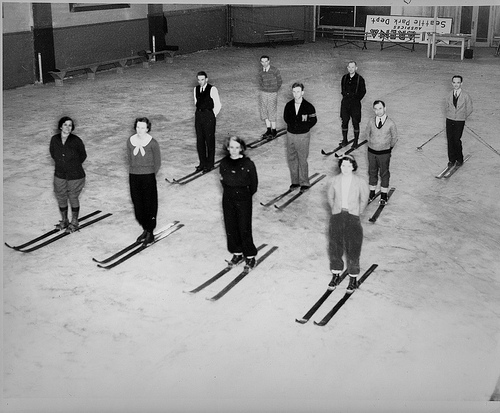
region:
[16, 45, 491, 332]
this group has been sentenced to ski lessons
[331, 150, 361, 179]
this young lady has a hair band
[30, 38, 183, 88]
a bench to one side of the rink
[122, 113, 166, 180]
this young lady's blouse has a bow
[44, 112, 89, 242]
this young lady is wearing jodhpurs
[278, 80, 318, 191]
this young man is wearing a varsity sweater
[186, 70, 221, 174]
this young man is nattily dressed in a vest and tie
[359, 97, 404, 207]
this young man is wearing a vest and tie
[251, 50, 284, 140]
this young man is wearing short pants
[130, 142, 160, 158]
part of a scarf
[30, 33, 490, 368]
The people are taking a ski class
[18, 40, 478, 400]
The people are all lined up together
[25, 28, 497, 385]
The people are all wearing ski boots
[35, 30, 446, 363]
The people are all using snow skis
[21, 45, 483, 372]
The people are planning to snow ski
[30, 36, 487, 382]
The people are male and female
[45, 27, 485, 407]
The people are standing in the snow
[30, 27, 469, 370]
The people are enjoying the day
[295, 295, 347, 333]
black skis on the ground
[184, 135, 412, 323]
two women on skis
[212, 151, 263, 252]
black suit on woman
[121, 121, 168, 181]
grey and white top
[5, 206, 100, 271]
black skis on the ground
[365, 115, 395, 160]
black tie under vest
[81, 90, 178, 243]
A person on a skate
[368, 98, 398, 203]
A person on a skate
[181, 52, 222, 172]
A person on a skate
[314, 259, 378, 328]
black ski on snow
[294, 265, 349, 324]
black ski on snow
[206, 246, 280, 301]
black ski on snow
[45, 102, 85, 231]
a person is standing up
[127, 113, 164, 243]
a person is standing up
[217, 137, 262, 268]
a person is standing up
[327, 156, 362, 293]
a person is standing up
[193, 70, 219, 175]
a person is standing up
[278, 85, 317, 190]
a person is standing up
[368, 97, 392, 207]
a person is standing up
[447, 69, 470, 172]
a person is standing up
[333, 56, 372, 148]
a person is standing up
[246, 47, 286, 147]
a person is standing up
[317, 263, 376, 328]
black ski on snow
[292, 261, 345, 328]
black ski on snow